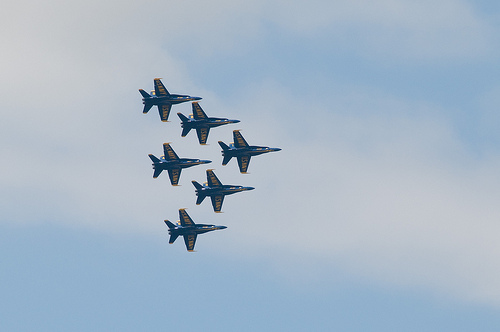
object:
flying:
[161, 206, 232, 256]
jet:
[163, 207, 228, 252]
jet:
[147, 142, 214, 187]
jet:
[216, 128, 283, 174]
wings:
[182, 234, 198, 252]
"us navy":
[178, 208, 196, 250]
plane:
[137, 76, 207, 122]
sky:
[0, 0, 499, 332]